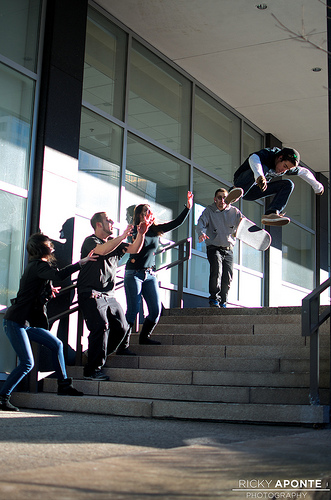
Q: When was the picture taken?
A: Daytime.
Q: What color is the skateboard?
A: Black.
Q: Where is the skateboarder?
A: In the air.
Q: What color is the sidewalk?
A: Gray.